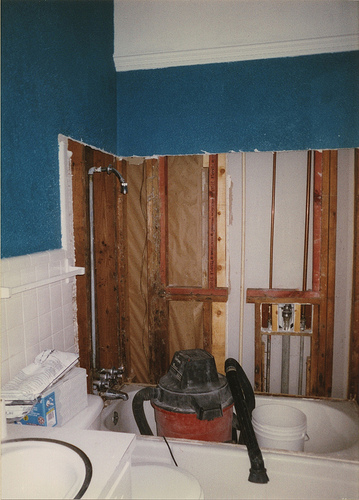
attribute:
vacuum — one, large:
[129, 345, 267, 483]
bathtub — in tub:
[48, 360, 310, 458]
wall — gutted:
[68, 138, 338, 400]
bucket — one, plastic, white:
[250, 400, 312, 453]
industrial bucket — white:
[247, 399, 312, 453]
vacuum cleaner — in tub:
[92, 330, 297, 497]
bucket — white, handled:
[248, 399, 309, 460]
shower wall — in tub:
[56, 129, 358, 403]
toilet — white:
[43, 390, 204, 497]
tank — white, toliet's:
[79, 389, 110, 443]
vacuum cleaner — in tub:
[132, 348, 267, 483]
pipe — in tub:
[86, 163, 102, 373]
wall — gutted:
[52, 133, 356, 347]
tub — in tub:
[89, 382, 357, 495]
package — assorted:
[0, 349, 88, 427]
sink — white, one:
[0, 438, 86, 498]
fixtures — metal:
[91, 361, 128, 402]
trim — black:
[4, 429, 93, 498]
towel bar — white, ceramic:
[13, 229, 99, 319]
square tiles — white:
[4, 249, 82, 399]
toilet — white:
[125, 451, 202, 498]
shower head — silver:
[96, 163, 124, 191]